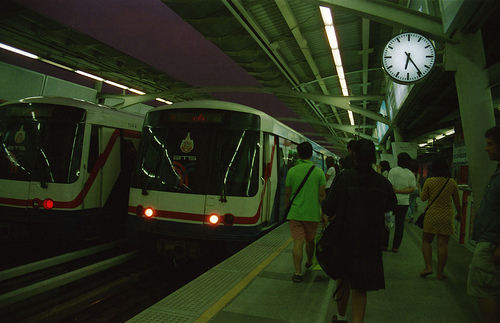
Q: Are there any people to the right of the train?
A: Yes, there is a person to the right of the train.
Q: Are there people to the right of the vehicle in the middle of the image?
A: Yes, there is a person to the right of the train.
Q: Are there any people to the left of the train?
A: No, the person is to the right of the train.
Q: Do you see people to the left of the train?
A: No, the person is to the right of the train.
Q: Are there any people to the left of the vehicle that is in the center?
A: No, the person is to the right of the train.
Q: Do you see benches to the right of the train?
A: No, there is a person to the right of the train.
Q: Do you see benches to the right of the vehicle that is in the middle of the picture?
A: No, there is a person to the right of the train.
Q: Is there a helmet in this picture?
A: No, there are no helmets.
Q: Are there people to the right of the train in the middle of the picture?
A: Yes, there is a person to the right of the train.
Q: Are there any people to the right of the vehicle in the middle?
A: Yes, there is a person to the right of the train.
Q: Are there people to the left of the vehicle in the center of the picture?
A: No, the person is to the right of the train.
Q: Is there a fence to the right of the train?
A: No, there is a person to the right of the train.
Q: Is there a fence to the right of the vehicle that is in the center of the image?
A: No, there is a person to the right of the train.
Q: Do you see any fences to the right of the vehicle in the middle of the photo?
A: No, there is a person to the right of the train.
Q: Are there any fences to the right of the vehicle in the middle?
A: No, there is a person to the right of the train.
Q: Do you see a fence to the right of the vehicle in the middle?
A: No, there is a person to the right of the train.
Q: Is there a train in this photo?
A: Yes, there is a train.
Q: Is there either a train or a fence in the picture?
A: Yes, there is a train.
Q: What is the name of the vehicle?
A: The vehicle is a train.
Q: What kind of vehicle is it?
A: The vehicle is a train.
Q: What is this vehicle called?
A: This is a train.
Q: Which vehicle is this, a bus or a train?
A: This is a train.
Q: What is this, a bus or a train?
A: This is a train.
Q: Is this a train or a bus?
A: This is a train.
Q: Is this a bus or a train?
A: This is a train.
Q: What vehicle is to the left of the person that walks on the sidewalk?
A: The vehicle is a train.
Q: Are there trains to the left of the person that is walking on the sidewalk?
A: Yes, there is a train to the left of the person.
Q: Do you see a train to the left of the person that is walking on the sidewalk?
A: Yes, there is a train to the left of the person.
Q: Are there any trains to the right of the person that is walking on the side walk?
A: No, the train is to the left of the person.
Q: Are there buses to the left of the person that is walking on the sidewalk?
A: No, there is a train to the left of the person.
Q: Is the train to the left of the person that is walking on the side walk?
A: Yes, the train is to the left of the person.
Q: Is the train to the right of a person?
A: No, the train is to the left of a person.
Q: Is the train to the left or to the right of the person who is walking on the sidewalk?
A: The train is to the left of the person.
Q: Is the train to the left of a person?
A: Yes, the train is to the left of a person.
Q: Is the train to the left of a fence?
A: No, the train is to the left of a person.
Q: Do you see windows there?
A: Yes, there is a window.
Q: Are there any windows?
A: Yes, there is a window.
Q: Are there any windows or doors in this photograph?
A: Yes, there is a window.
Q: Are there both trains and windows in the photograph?
A: Yes, there are both a window and a train.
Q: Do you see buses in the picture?
A: No, there are no buses.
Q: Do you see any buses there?
A: No, there are no buses.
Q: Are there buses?
A: No, there are no buses.